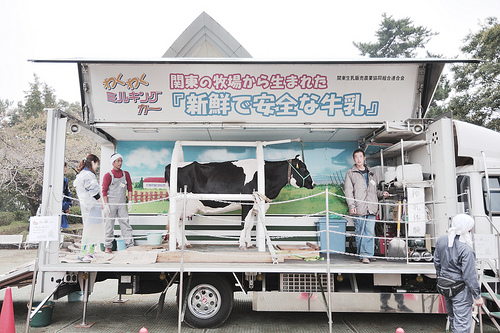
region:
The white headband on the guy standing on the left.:
[106, 141, 126, 163]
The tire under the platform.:
[171, 269, 263, 327]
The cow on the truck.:
[163, 138, 322, 249]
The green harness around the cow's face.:
[289, 160, 317, 188]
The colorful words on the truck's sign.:
[94, 68, 394, 128]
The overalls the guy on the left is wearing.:
[105, 170, 136, 245]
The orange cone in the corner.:
[0, 278, 17, 332]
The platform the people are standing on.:
[54, 242, 445, 285]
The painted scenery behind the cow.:
[115, 144, 370, 214]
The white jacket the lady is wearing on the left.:
[76, 160, 123, 243]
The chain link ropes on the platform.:
[61, 184, 471, 259]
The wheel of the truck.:
[169, 276, 231, 326]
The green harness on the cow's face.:
[291, 156, 316, 188]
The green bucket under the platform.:
[26, 289, 59, 331]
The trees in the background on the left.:
[6, 67, 94, 228]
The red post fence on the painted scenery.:
[130, 174, 169, 201]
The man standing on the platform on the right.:
[340, 145, 388, 263]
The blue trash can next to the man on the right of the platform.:
[311, 205, 353, 257]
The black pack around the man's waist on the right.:
[437, 275, 475, 305]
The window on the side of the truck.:
[476, 169, 498, 216]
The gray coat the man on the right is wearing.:
[344, 168, 383, 220]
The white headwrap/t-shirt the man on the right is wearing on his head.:
[445, 213, 477, 244]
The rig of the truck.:
[46, 100, 498, 260]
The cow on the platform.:
[162, 150, 306, 251]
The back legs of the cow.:
[165, 204, 197, 261]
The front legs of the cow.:
[241, 204, 261, 249]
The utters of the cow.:
[174, 195, 202, 225]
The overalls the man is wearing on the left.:
[105, 168, 134, 240]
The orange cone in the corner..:
[0, 285, 20, 331]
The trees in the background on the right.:
[354, 10, 498, 115]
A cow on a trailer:
[75, 124, 437, 283]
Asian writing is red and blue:
[100, 67, 392, 124]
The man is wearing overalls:
[96, 154, 146, 253]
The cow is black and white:
[157, 151, 312, 258]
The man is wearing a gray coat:
[340, 145, 378, 223]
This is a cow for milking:
[163, 156, 249, 232]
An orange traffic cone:
[1, 276, 26, 324]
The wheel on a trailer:
[172, 278, 243, 330]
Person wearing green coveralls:
[435, 232, 482, 329]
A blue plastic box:
[308, 204, 353, 259]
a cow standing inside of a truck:
[153, 153, 315, 248]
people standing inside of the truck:
[66, 143, 138, 255]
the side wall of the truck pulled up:
[41, 58, 476, 138]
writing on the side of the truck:
[102, 68, 404, 118]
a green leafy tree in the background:
[370, 13, 498, 123]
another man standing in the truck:
[336, 155, 386, 264]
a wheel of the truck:
[179, 270, 235, 326]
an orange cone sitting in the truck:
[1, 283, 23, 329]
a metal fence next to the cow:
[56, 187, 466, 253]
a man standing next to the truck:
[438, 214, 484, 326]